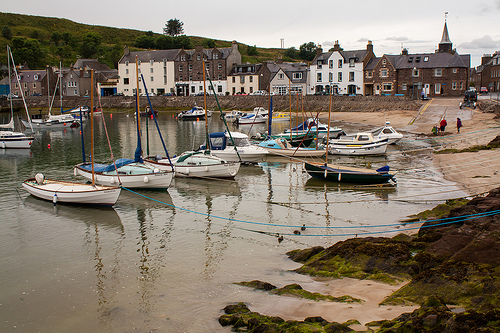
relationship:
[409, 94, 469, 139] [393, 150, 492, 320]
ramp to get to beach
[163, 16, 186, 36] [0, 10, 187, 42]
tree near a hill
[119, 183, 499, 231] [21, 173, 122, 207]
rope tying a white boat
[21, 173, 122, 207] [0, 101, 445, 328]
white boat in water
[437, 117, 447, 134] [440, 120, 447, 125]
person wearing red coat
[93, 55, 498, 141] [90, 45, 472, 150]
wall made of rock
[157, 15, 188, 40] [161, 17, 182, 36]
tree on ledge